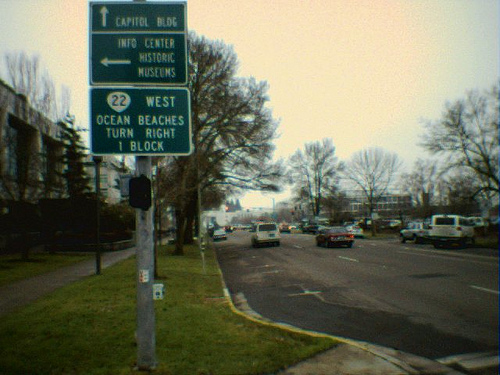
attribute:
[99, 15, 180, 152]
writing — white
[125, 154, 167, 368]
pole — gray, upright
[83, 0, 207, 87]
street sign — green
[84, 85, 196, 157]
street sign — green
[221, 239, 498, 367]
pavement — wet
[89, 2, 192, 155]
sign — green 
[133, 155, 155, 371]
pole — metal 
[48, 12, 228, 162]
signs — informational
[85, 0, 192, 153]
signs — green, white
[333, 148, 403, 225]
trees — leafless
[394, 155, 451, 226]
trees — leafless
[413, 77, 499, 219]
trees — leafless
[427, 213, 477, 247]
van — parked, white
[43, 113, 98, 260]
tree — pine 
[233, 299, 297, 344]
curb — yellow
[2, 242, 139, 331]
sidewalk — gray, cement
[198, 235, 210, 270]
parking meter — grey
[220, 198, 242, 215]
light — red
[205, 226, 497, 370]
street — city, pavement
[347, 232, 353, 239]
light — red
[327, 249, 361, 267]
street lines — white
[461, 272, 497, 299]
street lines — white